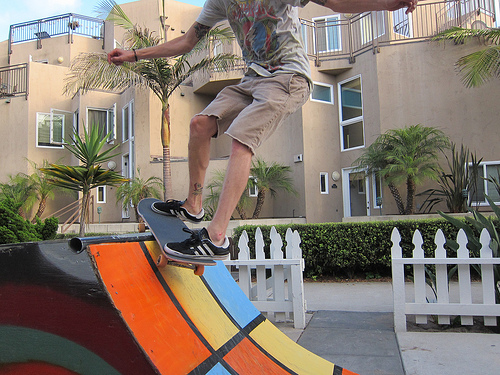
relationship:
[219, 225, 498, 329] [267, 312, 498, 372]
fence on sidewalk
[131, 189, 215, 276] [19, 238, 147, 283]
skateboard on jump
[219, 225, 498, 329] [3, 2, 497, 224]
fence around building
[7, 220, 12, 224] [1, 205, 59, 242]
leaf on tree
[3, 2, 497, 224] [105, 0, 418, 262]
building behind man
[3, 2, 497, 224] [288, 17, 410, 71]
building has balcony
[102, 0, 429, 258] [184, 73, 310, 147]
man wearing shorts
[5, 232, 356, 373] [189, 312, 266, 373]
ramp has line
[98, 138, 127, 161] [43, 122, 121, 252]
leaf on tree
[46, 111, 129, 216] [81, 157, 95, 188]
tree has leaf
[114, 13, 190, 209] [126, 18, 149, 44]
tree has leaf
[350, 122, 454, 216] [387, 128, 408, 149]
tree has leaf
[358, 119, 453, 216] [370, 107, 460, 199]
tree has leaf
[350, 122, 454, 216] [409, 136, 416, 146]
tree has leaf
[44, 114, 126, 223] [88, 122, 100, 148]
tree has leaf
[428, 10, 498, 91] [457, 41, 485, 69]
tree has green leaf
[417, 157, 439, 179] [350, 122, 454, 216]
green leaf on tree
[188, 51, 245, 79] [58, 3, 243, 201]
green leaf on tree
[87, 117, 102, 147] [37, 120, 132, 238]
green leaf on tree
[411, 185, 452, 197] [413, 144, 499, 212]
leaf on tree